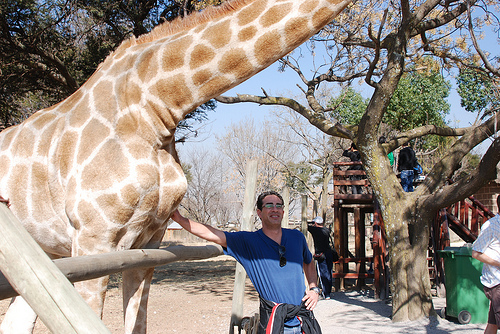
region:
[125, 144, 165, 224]
the giraffe has spot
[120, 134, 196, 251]
the giraffe has spot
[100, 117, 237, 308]
the giraffe has spot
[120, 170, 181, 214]
the giraffe has spot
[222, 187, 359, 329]
the man is wearing a blue shirt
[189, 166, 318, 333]
the man is smiling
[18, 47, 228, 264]
the giraffe is tan and brown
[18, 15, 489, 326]
they are at the zoo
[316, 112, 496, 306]
children are playing on the play structure.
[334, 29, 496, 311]
the tree is dying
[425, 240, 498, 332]
the trash can is green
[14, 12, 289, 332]
the giraffe is standing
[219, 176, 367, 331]
A man in a blue shirt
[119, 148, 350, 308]
A man touching a giraffe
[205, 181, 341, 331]
A man wearing glasses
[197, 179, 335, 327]
A man wearing a watch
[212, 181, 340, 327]
A man with sunglasses hanging from his shirt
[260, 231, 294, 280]
sunglasses on a blue shirt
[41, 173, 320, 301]
A wooden fence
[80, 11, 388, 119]
The neck of a giraffe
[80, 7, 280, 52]
The mane of a giraffe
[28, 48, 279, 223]
The spots of a giraffe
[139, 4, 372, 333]
man touching giraffe with hand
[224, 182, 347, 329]
man wearing blue shirt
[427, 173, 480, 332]
green trash can under tree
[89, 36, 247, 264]
giraffe with brown and white spots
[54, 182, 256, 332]
wood barrier between giraffe and man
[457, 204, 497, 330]
person wearing dark shorts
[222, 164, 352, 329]
black jacket with red stripe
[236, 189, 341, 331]
man wearing dark sunglasses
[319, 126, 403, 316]
redwood-looking viewing stand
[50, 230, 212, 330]
dirt on ground behind giraffe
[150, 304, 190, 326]
red gravel on the ground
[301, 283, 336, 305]
black and white watch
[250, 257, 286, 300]
lines in blue shirt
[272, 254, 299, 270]
black emblem around neck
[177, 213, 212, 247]
elbow of man's hand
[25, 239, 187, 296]
large wooden gray post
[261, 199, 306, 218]
stylish glasses on man's face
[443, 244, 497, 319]
large green plastic trash can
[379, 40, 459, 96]
golden leaves on the tree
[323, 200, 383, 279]
large red wooden post